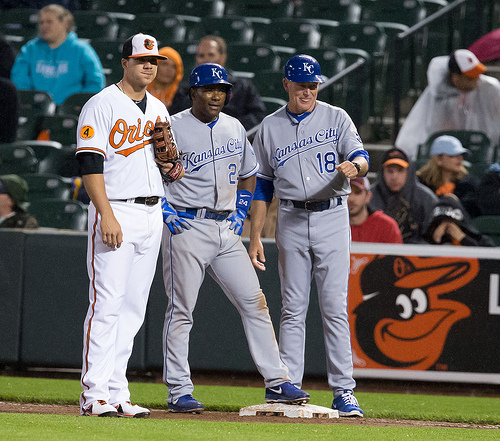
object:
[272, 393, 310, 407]
cleat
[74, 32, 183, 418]
baseball player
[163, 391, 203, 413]
shoes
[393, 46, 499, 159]
fan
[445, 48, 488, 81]
hat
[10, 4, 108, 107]
woman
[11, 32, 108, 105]
hoodie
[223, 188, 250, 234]
glove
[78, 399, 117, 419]
shoes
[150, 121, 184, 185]
mitt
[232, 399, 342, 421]
base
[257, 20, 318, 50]
chair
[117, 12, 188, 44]
chair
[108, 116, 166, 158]
logo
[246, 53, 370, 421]
coach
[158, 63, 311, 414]
runner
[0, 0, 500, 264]
stands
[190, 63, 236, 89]
helmet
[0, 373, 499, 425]
foul territory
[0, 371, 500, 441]
field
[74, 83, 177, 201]
jersey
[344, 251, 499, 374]
logo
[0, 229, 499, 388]
wall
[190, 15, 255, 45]
seat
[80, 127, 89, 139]
number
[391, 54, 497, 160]
poncho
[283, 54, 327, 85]
helmet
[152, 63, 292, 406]
uniform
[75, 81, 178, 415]
uniform